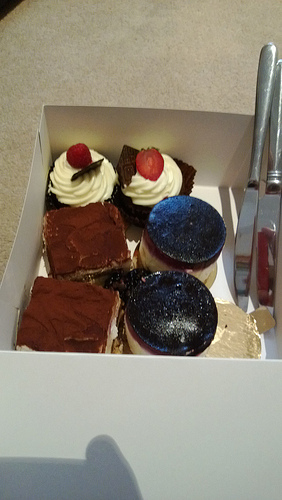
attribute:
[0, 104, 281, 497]
box — white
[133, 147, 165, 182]
strawberry — red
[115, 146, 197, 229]
cupcake — circular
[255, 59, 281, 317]
butter knife — shiny, silver, stainless steel, propped up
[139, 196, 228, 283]
dessert — purple, blue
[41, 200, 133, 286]
cake — square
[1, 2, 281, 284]
tabletop — white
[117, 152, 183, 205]
whipped cream — white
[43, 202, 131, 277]
frosting — chocolate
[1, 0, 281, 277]
carpet — ecru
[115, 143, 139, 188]
chocolate wafer — thin